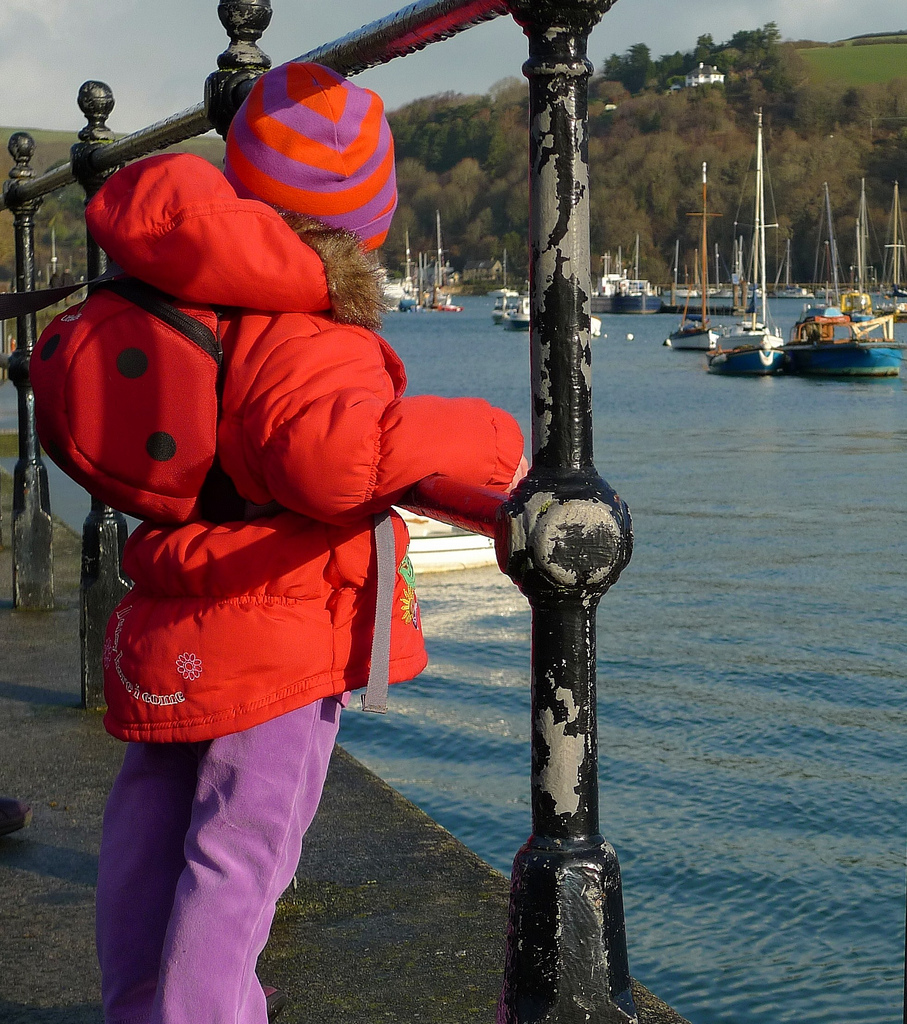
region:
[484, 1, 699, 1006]
a metal railing with chipped paint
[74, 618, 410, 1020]
purple pants on a little girl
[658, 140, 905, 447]
sailboats floating on the water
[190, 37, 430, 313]
stripped hat on a little girl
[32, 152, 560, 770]
red jacket on a little girl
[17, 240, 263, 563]
red and black backpack on her back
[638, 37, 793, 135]
a beautiful house up on a hill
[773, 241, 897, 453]
bottom of boat is blue in color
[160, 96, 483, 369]
brown fur around the hood of her jacket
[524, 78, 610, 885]
Paint chipping off of black railing.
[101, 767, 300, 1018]
Person wearing purple pants.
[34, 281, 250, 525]
Person wearing red and blackback pack on back.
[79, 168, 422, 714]
Person wearing puffy red jacket.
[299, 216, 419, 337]
Brown fur on hood of jacket.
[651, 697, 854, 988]
Water below is dark blue.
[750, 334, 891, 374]
Blue boats sitting in the water.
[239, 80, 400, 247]
Person wearing a purple and orange hat.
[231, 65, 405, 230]
Person wearing striped hat on head.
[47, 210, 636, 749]
Girl standing near railing close to edge.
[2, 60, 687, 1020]
young girl standing on concrete walkway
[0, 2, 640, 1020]
girl holding black railing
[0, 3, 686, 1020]
black railing anchored in walkway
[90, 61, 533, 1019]
young girl wearing red and purple striped hat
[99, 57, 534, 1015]
girl wearing purple pants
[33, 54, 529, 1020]
girl carrying red and black bookbag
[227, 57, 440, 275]
Person wearing hat on top of head.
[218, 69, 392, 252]
Person's hat is orange and purple.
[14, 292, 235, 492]
Red and black back pack on person's back.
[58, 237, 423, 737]
Person wearing large puffy coat.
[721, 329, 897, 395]
Blue sail boats in the water.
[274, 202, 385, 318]
Brown fur on the hood of person's coat.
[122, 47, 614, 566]
Person standing near black railing.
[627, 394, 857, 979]
Water below is dark blue.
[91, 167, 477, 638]
A kid in a red jacket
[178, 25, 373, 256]
A kid with a red and purple hat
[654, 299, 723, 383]
A white and green boat in the water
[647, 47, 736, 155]
A White House on top of the hill in the distant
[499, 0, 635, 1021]
a metal fence post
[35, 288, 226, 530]
a red lady bug back pack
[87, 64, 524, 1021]
a small girl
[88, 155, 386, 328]
a hood on a coat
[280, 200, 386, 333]
fur trim on a hood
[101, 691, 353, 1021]
purple pants on a girl